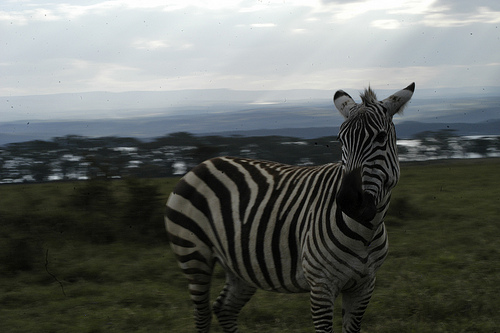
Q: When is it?
A: Day time.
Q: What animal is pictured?
A: A zebra.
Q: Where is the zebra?
A: On the grass.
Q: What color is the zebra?
A: Black and white.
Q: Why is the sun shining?
A: It is during the day.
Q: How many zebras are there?
A: One.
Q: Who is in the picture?
A: Only the zebra.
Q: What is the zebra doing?
A: Standing.